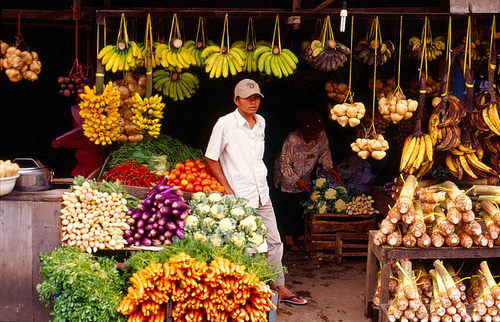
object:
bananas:
[98, 45, 116, 59]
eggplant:
[154, 194, 187, 199]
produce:
[37, 136, 291, 321]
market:
[0, 0, 500, 321]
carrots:
[164, 244, 171, 280]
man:
[205, 79, 307, 306]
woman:
[273, 117, 341, 252]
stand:
[365, 234, 498, 321]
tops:
[163, 240, 196, 266]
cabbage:
[208, 203, 231, 218]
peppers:
[144, 177, 153, 187]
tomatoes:
[185, 182, 193, 192]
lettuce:
[33, 244, 126, 322]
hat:
[234, 79, 266, 99]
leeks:
[367, 196, 372, 200]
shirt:
[204, 109, 269, 209]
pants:
[243, 199, 285, 286]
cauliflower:
[332, 199, 348, 212]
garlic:
[28, 74, 36, 81]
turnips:
[397, 174, 420, 213]